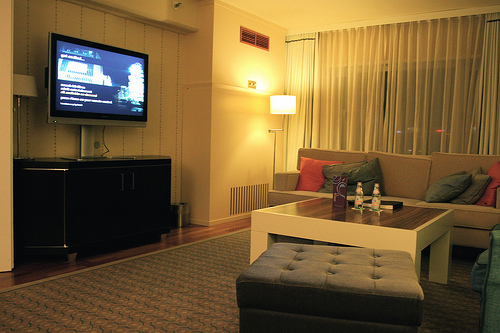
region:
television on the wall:
[21, 28, 198, 136]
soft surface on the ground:
[233, 233, 417, 317]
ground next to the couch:
[109, 264, 209, 331]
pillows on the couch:
[288, 146, 399, 196]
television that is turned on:
[21, 42, 170, 135]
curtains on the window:
[288, 60, 452, 133]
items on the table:
[322, 175, 404, 220]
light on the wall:
[255, 76, 305, 150]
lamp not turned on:
[0, 68, 53, 148]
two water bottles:
[341, 172, 391, 227]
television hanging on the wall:
[44, 30, 163, 145]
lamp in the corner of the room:
[265, 86, 297, 197]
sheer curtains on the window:
[307, 12, 499, 162]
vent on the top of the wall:
[235, 21, 280, 58]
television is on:
[44, 31, 166, 140]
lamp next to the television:
[15, 65, 42, 155]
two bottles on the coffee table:
[350, 176, 386, 215]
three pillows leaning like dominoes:
[410, 160, 499, 211]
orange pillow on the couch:
[294, 153, 335, 190]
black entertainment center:
[21, 153, 188, 270]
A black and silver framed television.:
[47, 36, 148, 124]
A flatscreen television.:
[50, 30, 149, 127]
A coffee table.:
[246, 183, 454, 292]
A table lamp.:
[9, 71, 41, 164]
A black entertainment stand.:
[21, 147, 169, 262]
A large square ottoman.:
[238, 236, 426, 318]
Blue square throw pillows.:
[322, 159, 467, 200]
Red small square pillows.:
[295, 157, 498, 204]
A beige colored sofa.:
[273, 147, 498, 247]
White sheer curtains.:
[320, 17, 482, 152]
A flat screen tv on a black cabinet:
[41, 25, 154, 125]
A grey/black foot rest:
[220, 230, 435, 330]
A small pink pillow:
[291, 150, 336, 195]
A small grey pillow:
[312, 156, 362, 191]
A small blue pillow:
[337, 155, 387, 205]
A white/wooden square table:
[240, 185, 451, 285]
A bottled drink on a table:
[350, 172, 365, 207]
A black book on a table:
[356, 187, 406, 212]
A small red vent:
[230, 20, 275, 55]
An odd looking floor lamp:
[250, 87, 300, 175]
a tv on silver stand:
[43, 30, 150, 152]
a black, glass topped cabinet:
[28, 151, 181, 253]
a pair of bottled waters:
[351, 179, 386, 216]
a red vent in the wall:
[236, 25, 273, 52]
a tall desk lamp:
[11, 72, 38, 163]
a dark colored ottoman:
[230, 233, 430, 329]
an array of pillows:
[290, 153, 392, 200]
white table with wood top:
[243, 189, 460, 289]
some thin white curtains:
[284, 13, 498, 167]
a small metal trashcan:
[174, 198, 191, 229]